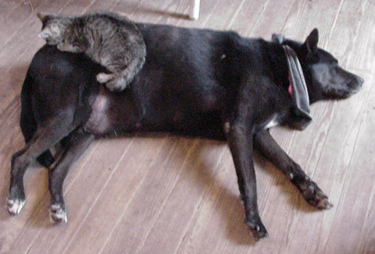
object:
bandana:
[270, 32, 313, 131]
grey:
[70, 21, 129, 46]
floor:
[0, 0, 375, 254]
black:
[163, 37, 248, 96]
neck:
[269, 40, 293, 117]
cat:
[36, 7, 149, 91]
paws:
[48, 203, 68, 224]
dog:
[0, 8, 363, 239]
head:
[35, 11, 66, 46]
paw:
[306, 188, 334, 211]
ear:
[298, 28, 320, 59]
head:
[291, 26, 365, 102]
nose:
[357, 75, 365, 87]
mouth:
[319, 81, 362, 98]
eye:
[330, 60, 338, 65]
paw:
[96, 72, 109, 82]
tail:
[106, 54, 149, 92]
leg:
[223, 113, 268, 238]